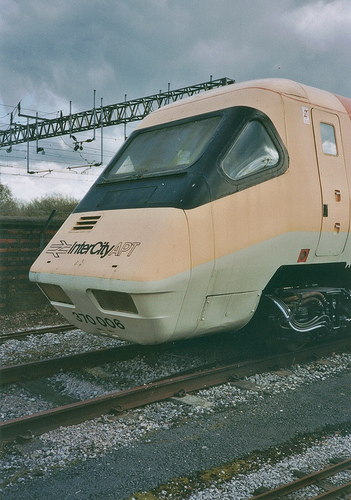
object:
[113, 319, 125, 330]
numbers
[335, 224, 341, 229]
handle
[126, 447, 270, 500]
moss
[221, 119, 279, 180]
windshield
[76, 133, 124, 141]
wires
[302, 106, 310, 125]
sticker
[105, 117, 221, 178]
windshield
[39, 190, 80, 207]
leafs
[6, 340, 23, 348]
stones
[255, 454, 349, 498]
track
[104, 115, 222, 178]
window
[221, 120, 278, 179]
window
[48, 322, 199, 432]
metal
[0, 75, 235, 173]
bridge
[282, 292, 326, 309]
tubes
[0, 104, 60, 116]
power wires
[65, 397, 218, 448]
gravel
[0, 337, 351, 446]
tracks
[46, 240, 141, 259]
logo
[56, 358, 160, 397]
gravel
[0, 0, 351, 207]
clouds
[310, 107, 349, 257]
door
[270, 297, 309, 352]
wheel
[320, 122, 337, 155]
side window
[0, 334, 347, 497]
ground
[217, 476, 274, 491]
rocks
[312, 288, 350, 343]
wheels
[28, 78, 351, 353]
train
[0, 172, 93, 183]
wires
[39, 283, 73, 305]
headlights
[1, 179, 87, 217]
trees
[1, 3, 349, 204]
sky